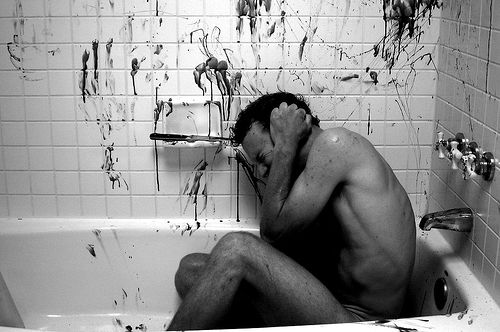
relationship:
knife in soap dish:
[145, 130, 227, 143] [157, 97, 227, 155]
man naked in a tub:
[164, 90, 427, 319] [8, 217, 480, 315]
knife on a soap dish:
[145, 130, 227, 143] [157, 97, 227, 155]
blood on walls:
[5, 5, 466, 221] [5, 6, 481, 283]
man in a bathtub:
[164, 90, 427, 319] [6, 215, 482, 322]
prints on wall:
[73, 35, 145, 155] [3, 2, 498, 302]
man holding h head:
[164, 90, 427, 319] [227, 84, 321, 182]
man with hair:
[164, 90, 427, 319] [221, 89, 315, 149]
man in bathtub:
[164, 90, 427, 319] [7, 205, 471, 319]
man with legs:
[164, 90, 427, 319] [164, 231, 351, 330]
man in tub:
[164, 90, 420, 331] [1, 216, 498, 328]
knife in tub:
[145, 130, 227, 143] [1, 216, 497, 332]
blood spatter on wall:
[78, 46, 102, 96] [3, 2, 498, 302]